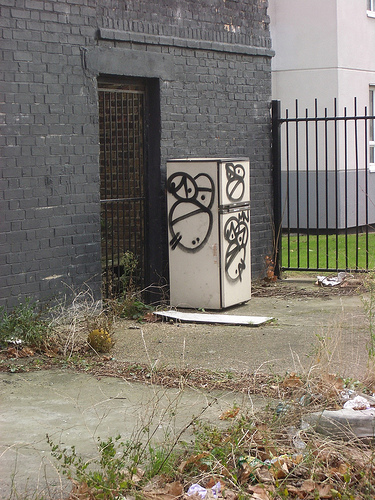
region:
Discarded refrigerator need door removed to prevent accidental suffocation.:
[162, 148, 258, 311]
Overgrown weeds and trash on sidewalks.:
[38, 317, 373, 487]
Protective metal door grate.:
[87, 73, 160, 306]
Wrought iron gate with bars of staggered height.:
[272, 88, 373, 273]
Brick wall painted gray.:
[178, 57, 259, 152]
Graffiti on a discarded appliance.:
[166, 163, 250, 287]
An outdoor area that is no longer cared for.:
[5, 41, 302, 467]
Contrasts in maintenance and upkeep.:
[153, 47, 373, 456]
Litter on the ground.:
[287, 380, 373, 452]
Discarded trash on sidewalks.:
[302, 272, 374, 470]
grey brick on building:
[8, 283, 40, 295]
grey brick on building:
[47, 276, 72, 287]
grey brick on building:
[5, 273, 23, 282]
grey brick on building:
[36, 266, 53, 276]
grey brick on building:
[46, 82, 65, 92]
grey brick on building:
[10, 27, 41, 41]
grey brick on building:
[80, 6, 96, 16]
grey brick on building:
[97, 39, 115, 45]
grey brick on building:
[114, 40, 133, 49]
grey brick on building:
[145, 44, 161, 51]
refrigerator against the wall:
[175, 148, 259, 307]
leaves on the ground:
[219, 424, 340, 497]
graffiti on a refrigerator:
[162, 165, 216, 254]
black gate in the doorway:
[88, 74, 166, 320]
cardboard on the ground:
[143, 296, 277, 341]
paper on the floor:
[314, 263, 353, 295]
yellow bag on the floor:
[78, 324, 119, 351]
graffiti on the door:
[216, 210, 256, 299]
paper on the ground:
[319, 253, 346, 296]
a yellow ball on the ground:
[88, 327, 119, 357]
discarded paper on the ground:
[185, 479, 227, 499]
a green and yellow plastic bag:
[239, 452, 278, 478]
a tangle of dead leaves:
[275, 447, 363, 495]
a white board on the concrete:
[160, 306, 266, 330]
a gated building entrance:
[97, 85, 168, 310]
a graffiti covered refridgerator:
[169, 153, 246, 309]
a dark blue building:
[6, 2, 272, 325]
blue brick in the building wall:
[8, 182, 62, 218]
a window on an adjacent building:
[364, 80, 373, 175]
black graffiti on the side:
[167, 169, 216, 248]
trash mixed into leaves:
[182, 451, 274, 499]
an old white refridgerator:
[163, 148, 259, 308]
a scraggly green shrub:
[57, 438, 151, 492]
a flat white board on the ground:
[154, 302, 272, 330]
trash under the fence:
[314, 273, 352, 286]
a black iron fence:
[277, 105, 369, 276]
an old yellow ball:
[84, 320, 117, 353]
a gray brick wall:
[176, 56, 264, 155]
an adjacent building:
[270, 0, 373, 244]